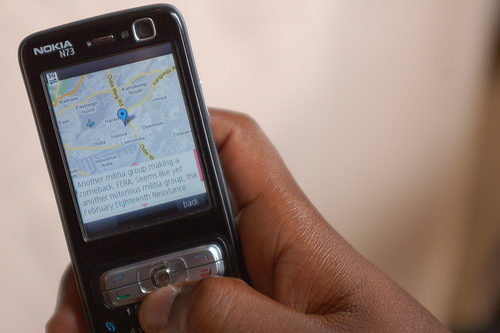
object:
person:
[44, 108, 457, 333]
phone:
[18, 3, 251, 333]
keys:
[96, 243, 233, 312]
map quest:
[47, 52, 213, 225]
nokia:
[33, 40, 75, 58]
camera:
[131, 17, 157, 42]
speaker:
[86, 34, 116, 47]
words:
[77, 158, 197, 216]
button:
[103, 244, 225, 307]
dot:
[117, 108, 127, 126]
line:
[193, 149, 206, 181]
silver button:
[151, 265, 175, 289]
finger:
[137, 274, 343, 331]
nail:
[144, 284, 180, 329]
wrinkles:
[180, 278, 291, 329]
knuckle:
[183, 274, 235, 330]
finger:
[207, 98, 301, 253]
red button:
[189, 261, 222, 282]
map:
[45, 53, 209, 223]